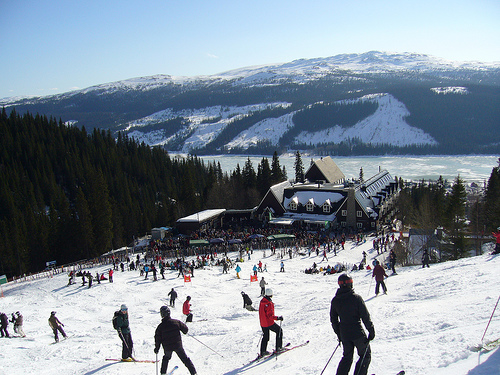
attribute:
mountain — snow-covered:
[190, 57, 472, 159]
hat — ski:
[115, 300, 128, 317]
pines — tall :
[1, 103, 296, 285]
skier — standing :
[44, 309, 74, 343]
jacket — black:
[331, 285, 368, 339]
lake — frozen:
[162, 147, 495, 192]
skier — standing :
[241, 254, 284, 365]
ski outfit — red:
[248, 283, 295, 358]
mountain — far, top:
[1, 43, 497, 153]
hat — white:
[264, 287, 273, 297]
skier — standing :
[278, 241, 406, 356]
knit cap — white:
[264, 288, 271, 298]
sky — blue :
[0, 0, 499, 102]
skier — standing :
[329, 274, 371, 373]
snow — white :
[0, 234, 497, 374]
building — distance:
[253, 147, 409, 238]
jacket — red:
[254, 298, 280, 333]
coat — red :
[259, 296, 275, 326]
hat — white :
[257, 286, 273, 296]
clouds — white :
[201, 45, 228, 65]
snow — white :
[243, 355, 303, 374]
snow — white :
[296, 304, 323, 340]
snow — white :
[25, 345, 92, 373]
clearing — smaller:
[433, 78, 470, 100]